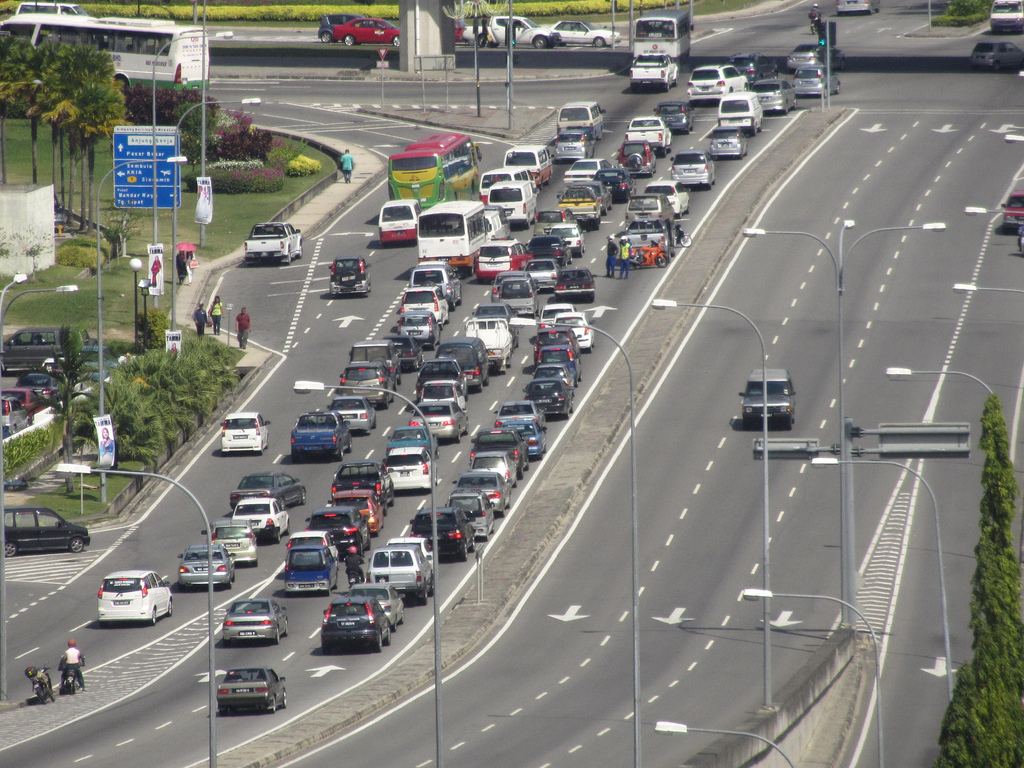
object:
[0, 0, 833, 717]
traffic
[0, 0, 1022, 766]
road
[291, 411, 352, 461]
truck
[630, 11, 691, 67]
bus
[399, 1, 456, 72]
bridge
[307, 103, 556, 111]
arrow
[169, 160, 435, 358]
sidewalk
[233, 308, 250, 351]
person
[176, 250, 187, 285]
person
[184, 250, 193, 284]
person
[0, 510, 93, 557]
van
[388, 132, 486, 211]
bus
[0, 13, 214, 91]
bus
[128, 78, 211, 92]
bottom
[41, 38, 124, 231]
palm tree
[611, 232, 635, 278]
man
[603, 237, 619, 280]
man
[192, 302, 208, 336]
person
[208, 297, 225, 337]
person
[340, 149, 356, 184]
guy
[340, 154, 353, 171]
shirt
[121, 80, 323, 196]
flower display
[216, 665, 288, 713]
car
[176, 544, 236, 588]
car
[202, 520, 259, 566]
car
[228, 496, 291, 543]
car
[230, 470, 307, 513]
car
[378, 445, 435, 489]
car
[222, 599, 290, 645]
car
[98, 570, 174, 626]
car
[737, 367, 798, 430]
car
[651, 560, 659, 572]
line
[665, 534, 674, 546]
line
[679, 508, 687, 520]
line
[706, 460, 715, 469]
line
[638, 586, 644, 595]
line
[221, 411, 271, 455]
car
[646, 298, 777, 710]
pole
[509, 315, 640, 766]
pole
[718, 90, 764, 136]
cars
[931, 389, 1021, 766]
tree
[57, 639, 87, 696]
man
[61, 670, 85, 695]
motorcycle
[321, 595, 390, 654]
car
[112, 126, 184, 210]
sign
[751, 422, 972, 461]
road sign